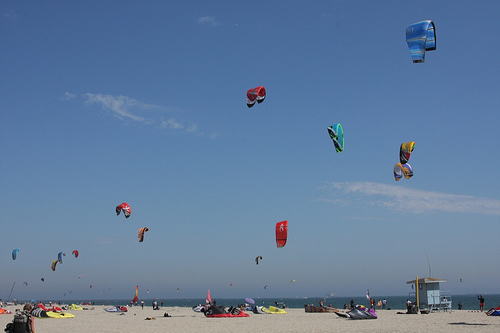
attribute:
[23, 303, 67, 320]
person — sunbathing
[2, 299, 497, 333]
beach — filled, sandy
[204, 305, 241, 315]
person — sunbathing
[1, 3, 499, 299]
sky — blue, hazy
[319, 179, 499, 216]
cloud — white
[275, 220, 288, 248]
kite — flying, red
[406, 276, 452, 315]
tower — tall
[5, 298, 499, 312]
ocean — blue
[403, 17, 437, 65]
kite — flying, blue, bright blue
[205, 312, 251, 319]
towel — red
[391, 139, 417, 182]
kite — different, flying, yellow, multi colored, colorful